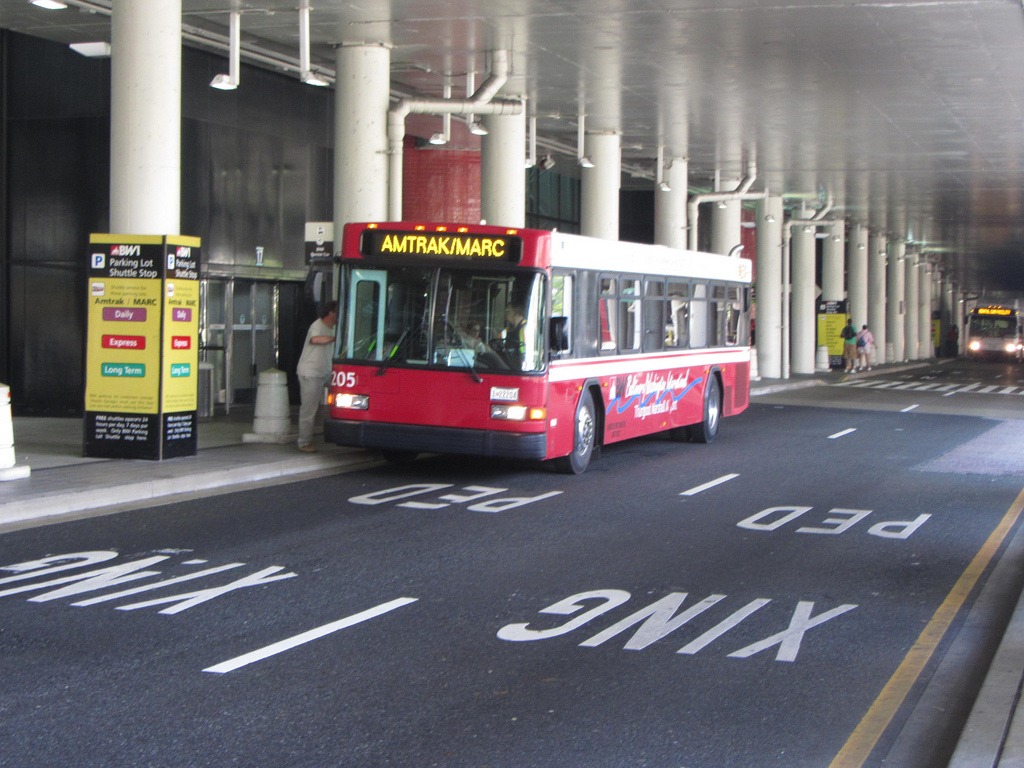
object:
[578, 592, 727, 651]
letter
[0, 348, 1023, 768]
road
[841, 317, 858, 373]
people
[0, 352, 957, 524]
sidewalk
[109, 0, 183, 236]
column